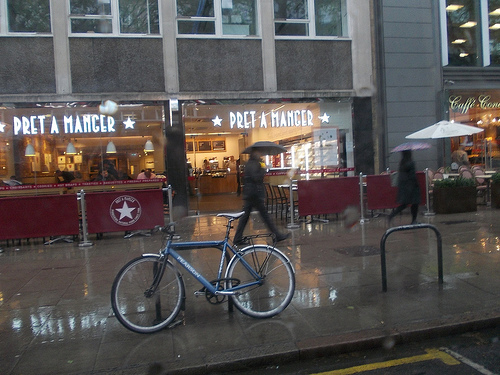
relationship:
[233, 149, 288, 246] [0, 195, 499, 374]
man walking on sidewalk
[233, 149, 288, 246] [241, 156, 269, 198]
man wearing jacket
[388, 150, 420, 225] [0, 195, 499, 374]
woman walking on sidewalk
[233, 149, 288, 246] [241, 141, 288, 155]
man has an umbrella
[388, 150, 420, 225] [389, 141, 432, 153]
woman under umbrella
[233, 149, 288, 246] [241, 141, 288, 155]
man holding umbrella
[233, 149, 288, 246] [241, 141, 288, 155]
man carrying umbrella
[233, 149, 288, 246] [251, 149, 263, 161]
man has a head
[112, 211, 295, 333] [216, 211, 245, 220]
bicycle has a seat